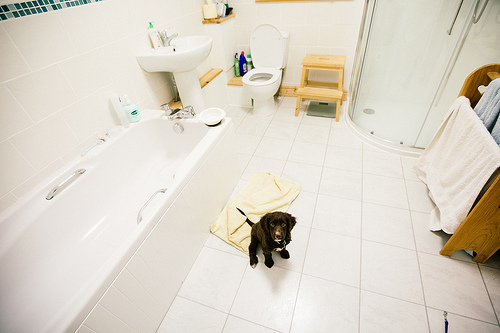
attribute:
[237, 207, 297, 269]
puppy — black, brown, small, white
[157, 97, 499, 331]
floor — tiled, white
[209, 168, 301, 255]
towel — yellow, beige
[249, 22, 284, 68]
toilet lid — raised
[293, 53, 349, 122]
step stool — wooden, short, tan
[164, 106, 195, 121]
faucet — silver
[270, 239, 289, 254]
puppy's chest — white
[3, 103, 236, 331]
bathtub — white, large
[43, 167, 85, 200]
handle — silver, white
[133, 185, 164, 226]
handle — silver, white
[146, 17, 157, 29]
lid — green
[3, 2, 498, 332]
bathroom — tiled, white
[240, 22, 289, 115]
toilet — white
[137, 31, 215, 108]
sink — white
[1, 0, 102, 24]
tiles — green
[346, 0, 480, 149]
shower door — glass, rounded, clear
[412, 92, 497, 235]
towel — white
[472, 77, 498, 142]
towel — blue